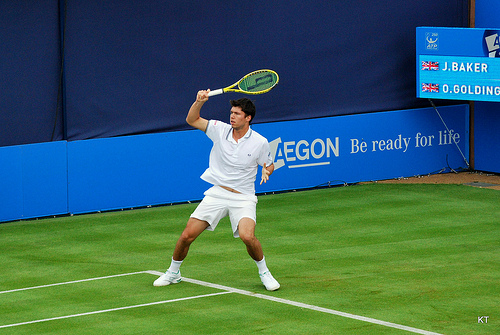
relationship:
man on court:
[152, 89, 279, 292] [2, 172, 497, 335]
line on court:
[145, 268, 439, 335] [2, 172, 497, 335]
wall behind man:
[0, 0, 472, 149] [152, 89, 279, 292]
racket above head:
[207, 68, 281, 97] [229, 99, 256, 131]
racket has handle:
[207, 68, 281, 97] [206, 86, 224, 98]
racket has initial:
[207, 68, 281, 97] [248, 72, 274, 90]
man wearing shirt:
[152, 89, 279, 292] [199, 117, 275, 196]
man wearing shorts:
[152, 89, 279, 292] [190, 185, 260, 239]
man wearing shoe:
[152, 89, 279, 292] [258, 269, 281, 291]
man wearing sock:
[152, 89, 279, 292] [254, 253, 268, 275]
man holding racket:
[152, 89, 279, 292] [207, 68, 281, 97]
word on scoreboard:
[441, 60, 488, 74] [414, 25, 499, 104]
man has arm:
[152, 89, 279, 292] [183, 101, 221, 136]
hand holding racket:
[196, 88, 210, 103] [207, 68, 281, 97]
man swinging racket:
[152, 89, 279, 292] [207, 68, 281, 97]